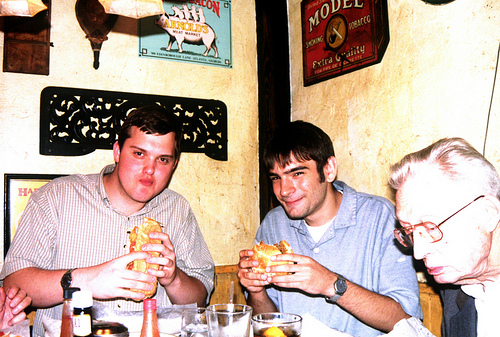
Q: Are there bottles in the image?
A: Yes, there is a bottle.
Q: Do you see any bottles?
A: Yes, there is a bottle.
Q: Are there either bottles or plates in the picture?
A: Yes, there is a bottle.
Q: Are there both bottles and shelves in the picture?
A: No, there is a bottle but no shelves.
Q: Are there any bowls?
A: No, there are no bowls.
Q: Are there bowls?
A: No, there are no bowls.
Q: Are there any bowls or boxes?
A: No, there are no bowls or boxes.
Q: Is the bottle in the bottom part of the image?
A: Yes, the bottle is in the bottom of the image.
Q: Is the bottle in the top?
A: No, the bottle is in the bottom of the image.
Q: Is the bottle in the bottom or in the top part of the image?
A: The bottle is in the bottom of the image.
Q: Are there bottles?
A: Yes, there is a bottle.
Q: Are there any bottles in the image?
A: Yes, there is a bottle.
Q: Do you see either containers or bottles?
A: Yes, there is a bottle.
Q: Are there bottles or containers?
A: Yes, there is a bottle.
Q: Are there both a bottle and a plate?
A: No, there is a bottle but no plates.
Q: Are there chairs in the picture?
A: No, there are no chairs.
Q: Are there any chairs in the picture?
A: No, there are no chairs.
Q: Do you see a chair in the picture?
A: No, there are no chairs.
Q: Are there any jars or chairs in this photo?
A: No, there are no chairs or jars.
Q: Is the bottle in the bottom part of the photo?
A: Yes, the bottle is in the bottom of the image.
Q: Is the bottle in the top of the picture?
A: No, the bottle is in the bottom of the image.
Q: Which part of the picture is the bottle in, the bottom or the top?
A: The bottle is in the bottom of the image.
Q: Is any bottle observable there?
A: Yes, there is a bottle.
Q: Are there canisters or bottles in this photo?
A: Yes, there is a bottle.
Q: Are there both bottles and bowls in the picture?
A: No, there is a bottle but no bowls.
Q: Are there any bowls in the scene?
A: No, there are no bowls.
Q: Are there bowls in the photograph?
A: No, there are no bowls.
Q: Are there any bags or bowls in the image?
A: No, there are no bowls or bags.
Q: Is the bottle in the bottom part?
A: Yes, the bottle is in the bottom of the image.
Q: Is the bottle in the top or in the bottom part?
A: The bottle is in the bottom of the image.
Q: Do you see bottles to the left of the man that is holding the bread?
A: Yes, there is a bottle to the left of the man.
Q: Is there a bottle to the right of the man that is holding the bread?
A: No, the bottle is to the left of the man.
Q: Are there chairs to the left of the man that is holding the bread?
A: No, there is a bottle to the left of the man.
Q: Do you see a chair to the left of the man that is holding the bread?
A: No, there is a bottle to the left of the man.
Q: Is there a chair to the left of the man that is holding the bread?
A: No, there is a bottle to the left of the man.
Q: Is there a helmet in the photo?
A: No, there are no helmets.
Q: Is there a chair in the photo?
A: No, there are no chairs.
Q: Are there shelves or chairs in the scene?
A: No, there are no chairs or shelves.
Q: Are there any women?
A: No, there are no women.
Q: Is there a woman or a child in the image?
A: No, there are no women or children.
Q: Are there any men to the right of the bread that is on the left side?
A: Yes, there is a man to the right of the bread.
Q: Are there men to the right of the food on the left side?
A: Yes, there is a man to the right of the bread.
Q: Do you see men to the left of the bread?
A: No, the man is to the right of the bread.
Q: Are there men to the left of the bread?
A: No, the man is to the right of the bread.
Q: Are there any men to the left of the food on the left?
A: No, the man is to the right of the bread.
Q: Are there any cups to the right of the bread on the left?
A: No, there is a man to the right of the bread.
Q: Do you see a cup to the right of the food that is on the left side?
A: No, there is a man to the right of the bread.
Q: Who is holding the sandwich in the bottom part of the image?
A: The man is holding the sandwich.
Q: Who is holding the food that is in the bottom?
A: The man is holding the sandwich.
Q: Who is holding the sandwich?
A: The man is holding the sandwich.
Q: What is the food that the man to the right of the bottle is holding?
A: The food is a sandwich.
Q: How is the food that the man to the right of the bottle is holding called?
A: The food is a sandwich.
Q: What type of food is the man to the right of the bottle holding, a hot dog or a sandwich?
A: The man is holding a sandwich.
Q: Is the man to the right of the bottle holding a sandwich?
A: Yes, the man is holding a sandwich.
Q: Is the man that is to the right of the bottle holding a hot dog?
A: No, the man is holding a sandwich.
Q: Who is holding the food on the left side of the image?
A: The man is holding the bread.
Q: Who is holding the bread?
A: The man is holding the bread.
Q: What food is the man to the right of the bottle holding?
A: The man is holding the bread.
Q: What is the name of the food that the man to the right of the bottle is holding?
A: The food is a bread.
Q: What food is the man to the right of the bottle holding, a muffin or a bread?
A: The man is holding a bread.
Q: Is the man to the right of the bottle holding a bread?
A: Yes, the man is holding a bread.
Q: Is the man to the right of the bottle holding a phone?
A: No, the man is holding a bread.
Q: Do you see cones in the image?
A: No, there are no cones.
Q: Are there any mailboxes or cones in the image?
A: No, there are no cones or mailboxes.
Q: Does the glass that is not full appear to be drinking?
A: Yes, the glass is drinking.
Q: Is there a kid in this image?
A: No, there are no children.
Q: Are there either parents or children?
A: No, there are no children or parents.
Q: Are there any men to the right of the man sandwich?
A: Yes, there is a man to the right of the sandwich.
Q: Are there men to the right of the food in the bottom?
A: Yes, there is a man to the right of the sandwich.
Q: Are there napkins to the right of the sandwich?
A: No, there is a man to the right of the sandwich.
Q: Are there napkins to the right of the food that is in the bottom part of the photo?
A: No, there is a man to the right of the sandwich.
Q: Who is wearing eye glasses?
A: The man is wearing eye glasses.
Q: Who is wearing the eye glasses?
A: The man is wearing eye glasses.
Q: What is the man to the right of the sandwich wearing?
A: The man is wearing eyeglasses.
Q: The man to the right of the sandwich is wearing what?
A: The man is wearing eyeglasses.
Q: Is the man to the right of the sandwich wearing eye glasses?
A: Yes, the man is wearing eye glasses.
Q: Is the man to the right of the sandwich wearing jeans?
A: No, the man is wearing eye glasses.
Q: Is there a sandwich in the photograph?
A: Yes, there is a sandwich.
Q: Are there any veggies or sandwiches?
A: Yes, there is a sandwich.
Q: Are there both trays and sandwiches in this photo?
A: No, there is a sandwich but no trays.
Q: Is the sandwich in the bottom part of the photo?
A: Yes, the sandwich is in the bottom of the image.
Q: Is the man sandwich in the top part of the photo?
A: No, the sandwich is in the bottom of the image.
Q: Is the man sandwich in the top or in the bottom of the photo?
A: The sandwich is in the bottom of the image.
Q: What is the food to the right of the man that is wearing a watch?
A: The food is a sandwich.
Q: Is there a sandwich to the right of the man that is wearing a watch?
A: Yes, there is a sandwich to the right of the man.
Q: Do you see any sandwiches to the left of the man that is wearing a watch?
A: No, the sandwich is to the right of the man.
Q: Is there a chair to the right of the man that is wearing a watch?
A: No, there is a sandwich to the right of the man.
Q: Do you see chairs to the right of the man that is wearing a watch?
A: No, there is a sandwich to the right of the man.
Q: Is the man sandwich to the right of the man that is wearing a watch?
A: Yes, the sandwich is to the right of the man.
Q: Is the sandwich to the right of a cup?
A: No, the sandwich is to the right of the man.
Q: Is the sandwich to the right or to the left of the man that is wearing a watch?
A: The sandwich is to the right of the man.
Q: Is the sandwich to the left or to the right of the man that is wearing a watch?
A: The sandwich is to the right of the man.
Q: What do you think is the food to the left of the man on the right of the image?
A: The food is a sandwich.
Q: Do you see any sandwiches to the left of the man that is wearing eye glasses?
A: Yes, there is a sandwich to the left of the man.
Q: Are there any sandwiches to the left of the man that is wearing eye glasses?
A: Yes, there is a sandwich to the left of the man.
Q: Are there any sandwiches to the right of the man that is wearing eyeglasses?
A: No, the sandwich is to the left of the man.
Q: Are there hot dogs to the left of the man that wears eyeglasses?
A: No, there is a sandwich to the left of the man.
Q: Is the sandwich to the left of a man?
A: Yes, the sandwich is to the left of a man.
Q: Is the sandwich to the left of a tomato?
A: No, the sandwich is to the left of a man.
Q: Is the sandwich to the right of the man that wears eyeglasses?
A: No, the sandwich is to the left of the man.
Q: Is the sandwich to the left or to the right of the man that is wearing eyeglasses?
A: The sandwich is to the left of the man.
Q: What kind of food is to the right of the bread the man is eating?
A: The food is a sandwich.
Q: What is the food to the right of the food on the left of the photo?
A: The food is a sandwich.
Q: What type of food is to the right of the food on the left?
A: The food is a sandwich.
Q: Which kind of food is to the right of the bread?
A: The food is a sandwich.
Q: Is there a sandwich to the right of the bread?
A: Yes, there is a sandwich to the right of the bread.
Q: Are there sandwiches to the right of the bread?
A: Yes, there is a sandwich to the right of the bread.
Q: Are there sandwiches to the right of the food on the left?
A: Yes, there is a sandwich to the right of the bread.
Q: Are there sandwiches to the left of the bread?
A: No, the sandwich is to the right of the bread.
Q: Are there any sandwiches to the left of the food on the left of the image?
A: No, the sandwich is to the right of the bread.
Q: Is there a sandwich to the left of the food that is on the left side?
A: No, the sandwich is to the right of the bread.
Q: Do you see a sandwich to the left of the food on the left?
A: No, the sandwich is to the right of the bread.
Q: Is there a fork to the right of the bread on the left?
A: No, there is a sandwich to the right of the bread.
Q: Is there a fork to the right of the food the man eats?
A: No, there is a sandwich to the right of the bread.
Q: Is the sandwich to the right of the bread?
A: Yes, the sandwich is to the right of the bread.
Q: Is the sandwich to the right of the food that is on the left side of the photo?
A: Yes, the sandwich is to the right of the bread.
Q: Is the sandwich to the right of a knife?
A: No, the sandwich is to the right of the bread.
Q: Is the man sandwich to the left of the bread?
A: No, the sandwich is to the right of the bread.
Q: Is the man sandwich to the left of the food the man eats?
A: No, the sandwich is to the right of the bread.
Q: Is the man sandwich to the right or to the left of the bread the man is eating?
A: The sandwich is to the right of the bread.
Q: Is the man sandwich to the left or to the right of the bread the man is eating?
A: The sandwich is to the right of the bread.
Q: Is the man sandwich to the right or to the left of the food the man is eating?
A: The sandwich is to the right of the bread.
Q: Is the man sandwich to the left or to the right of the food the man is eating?
A: The sandwich is to the right of the bread.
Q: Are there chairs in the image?
A: No, there are no chairs.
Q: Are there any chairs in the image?
A: No, there are no chairs.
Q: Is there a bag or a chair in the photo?
A: No, there are no chairs or bags.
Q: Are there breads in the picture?
A: Yes, there is a bread.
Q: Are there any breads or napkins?
A: Yes, there is a bread.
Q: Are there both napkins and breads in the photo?
A: No, there is a bread but no napkins.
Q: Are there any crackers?
A: No, there are no crackers.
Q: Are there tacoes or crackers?
A: No, there are no crackers or tacoes.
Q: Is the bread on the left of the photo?
A: Yes, the bread is on the left of the image.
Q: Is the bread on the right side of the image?
A: No, the bread is on the left of the image.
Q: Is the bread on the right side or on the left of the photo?
A: The bread is on the left of the image.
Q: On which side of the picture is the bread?
A: The bread is on the left of the image.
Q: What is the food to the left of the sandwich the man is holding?
A: The food is a bread.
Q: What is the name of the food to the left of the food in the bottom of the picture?
A: The food is a bread.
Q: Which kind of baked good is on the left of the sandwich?
A: The food is a bread.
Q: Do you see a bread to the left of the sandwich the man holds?
A: Yes, there is a bread to the left of the sandwich.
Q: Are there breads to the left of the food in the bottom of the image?
A: Yes, there is a bread to the left of the sandwich.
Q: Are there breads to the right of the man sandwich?
A: No, the bread is to the left of the sandwich.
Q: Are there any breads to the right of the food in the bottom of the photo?
A: No, the bread is to the left of the sandwich.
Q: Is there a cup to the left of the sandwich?
A: No, there is a bread to the left of the sandwich.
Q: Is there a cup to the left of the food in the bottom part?
A: No, there is a bread to the left of the sandwich.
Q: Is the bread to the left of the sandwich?
A: Yes, the bread is to the left of the sandwich.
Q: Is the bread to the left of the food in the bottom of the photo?
A: Yes, the bread is to the left of the sandwich.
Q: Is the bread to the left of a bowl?
A: No, the bread is to the left of the sandwich.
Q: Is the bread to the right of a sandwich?
A: No, the bread is to the left of a sandwich.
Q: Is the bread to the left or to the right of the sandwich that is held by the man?
A: The bread is to the left of the sandwich.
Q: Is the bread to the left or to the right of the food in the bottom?
A: The bread is to the left of the sandwich.